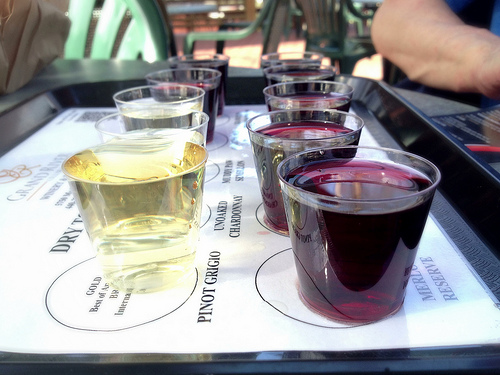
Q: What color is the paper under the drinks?
A: White.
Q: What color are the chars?
A: Green.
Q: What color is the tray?
A: Black.